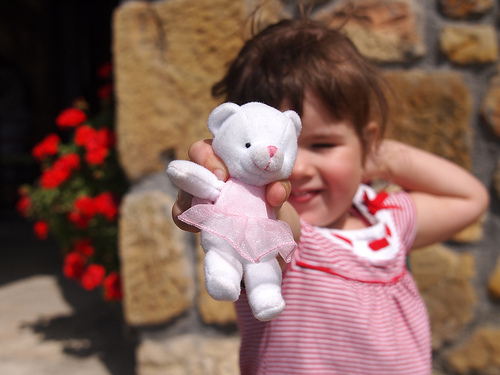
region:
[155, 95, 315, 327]
The white teddy bear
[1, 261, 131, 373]
The concrete floor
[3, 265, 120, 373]
A concrete floor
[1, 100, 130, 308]
A area of red roses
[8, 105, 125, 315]
The bunch of red roses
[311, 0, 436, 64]
tan rock on the wall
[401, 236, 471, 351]
tan rock on the wall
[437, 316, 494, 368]
tan rock on the wall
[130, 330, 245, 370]
tan rock on the wall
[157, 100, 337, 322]
small pink and white bear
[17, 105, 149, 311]
red flowers on plant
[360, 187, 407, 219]
red bow on shirt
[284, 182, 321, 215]
child's tongue is sticking out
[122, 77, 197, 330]
rock wall in background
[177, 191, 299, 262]
pink tutu on bear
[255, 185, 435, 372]
red and white striped shirt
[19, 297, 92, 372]
shadow of plant on ground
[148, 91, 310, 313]
girl holding bear in left hand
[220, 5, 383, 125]
girl has brown hair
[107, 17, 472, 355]
A little girl with a teddy bear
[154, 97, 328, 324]
a teddy bear in a tutu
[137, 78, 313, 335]
a teddy bear in a pink tutu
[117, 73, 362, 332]
a white teddy bear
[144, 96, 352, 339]
a white teddy bear in a girls hand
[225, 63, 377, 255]
a girl with her tongue out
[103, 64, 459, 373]
a girl in a red and white striped top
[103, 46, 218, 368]
a stone wall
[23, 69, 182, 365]
red flowers nex to a stone wall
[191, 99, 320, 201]
a white teddy bear with a pink nose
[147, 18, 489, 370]
a little girl wearing a red striped dress holding up a white teddy bear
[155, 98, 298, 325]
a white teddy bear wearing a pink ballerina outfit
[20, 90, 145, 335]
a pot of red flowers next to a stone wall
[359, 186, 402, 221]
a bright red bow on the little girl's dress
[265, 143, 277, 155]
a small pink nose on the white teddy bear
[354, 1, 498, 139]
a wall made of large stones behind the little gril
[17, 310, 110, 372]
a shadow of the flowers on the ground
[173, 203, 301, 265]
a lace pink skirt on the white teddy bear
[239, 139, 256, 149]
a small black eye on the white teddy bear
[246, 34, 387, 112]
the little girl's light brown hair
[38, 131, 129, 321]
Red flowers in pot.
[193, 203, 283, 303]
Bear wearing pink dress.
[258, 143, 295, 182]
Bear has pink nose.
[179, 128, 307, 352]
Stuffed animal is white.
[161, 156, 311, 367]
Girl is holding stuffed animal.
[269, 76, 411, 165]
Girl has brown hair.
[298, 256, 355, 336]
Girl is wearing red and white striped shirt.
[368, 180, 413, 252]
Red bow on shirt.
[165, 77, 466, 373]
Girl standing in front of stone wall.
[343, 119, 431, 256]
Girl has hand behind head.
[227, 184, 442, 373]
The red and white striped shirt the little girl is wearing.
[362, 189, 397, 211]
The red bow on the little girl's shirt.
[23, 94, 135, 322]
The red flowers to the left of the rock wall.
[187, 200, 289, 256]
The pink tutu on the little bear.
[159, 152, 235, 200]
The bear's left arm.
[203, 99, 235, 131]
The bear's left ear.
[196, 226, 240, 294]
The bear's left leg.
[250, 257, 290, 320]
The bear's right leg.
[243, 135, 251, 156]
The little black eye of the bear.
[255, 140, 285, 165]
The pink nose of the bear.